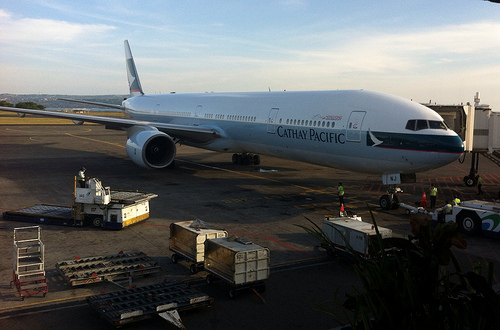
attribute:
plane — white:
[42, 35, 466, 205]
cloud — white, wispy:
[23, 19, 119, 39]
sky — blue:
[138, 10, 313, 58]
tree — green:
[14, 98, 47, 123]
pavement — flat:
[175, 180, 233, 227]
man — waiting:
[75, 165, 87, 190]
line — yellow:
[83, 132, 104, 145]